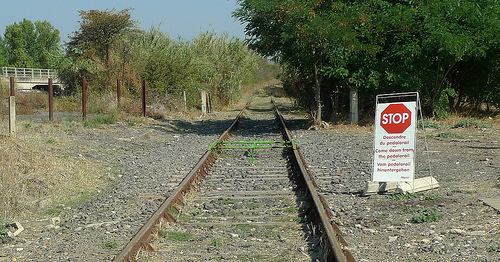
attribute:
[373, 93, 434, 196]
holder — metal, framed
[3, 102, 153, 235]
grass — browning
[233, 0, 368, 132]
tree — deciduous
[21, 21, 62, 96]
tree — deciduous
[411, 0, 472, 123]
tree — deciduous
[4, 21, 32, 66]
tree — deciduous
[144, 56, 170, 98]
tree — deciduous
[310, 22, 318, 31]
leaf — green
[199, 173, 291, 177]
tie — wooden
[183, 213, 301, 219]
tie — wooden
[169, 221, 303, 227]
tie — wooden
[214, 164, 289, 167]
tie — wooden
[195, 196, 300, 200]
tie — wooden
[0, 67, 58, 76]
rail — metal